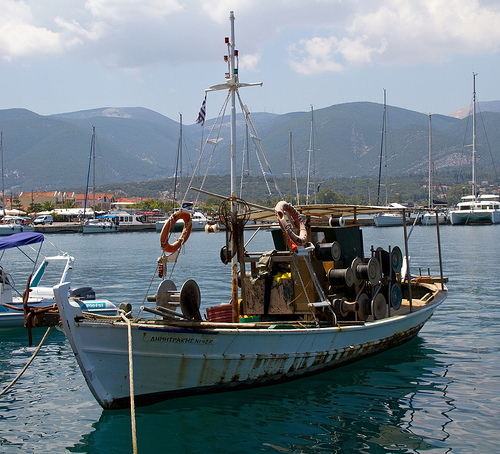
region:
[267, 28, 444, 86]
The sky is clear.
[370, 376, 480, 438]
The water is calm.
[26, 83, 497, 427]
Many boats are in the water.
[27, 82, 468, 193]
The mountains are far.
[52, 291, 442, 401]
The boat is white.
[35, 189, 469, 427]
The boat is in the water.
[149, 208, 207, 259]
The life saver is red.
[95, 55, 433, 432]
The boat has equipment on it.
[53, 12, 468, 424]
The boat is tethered to the shore.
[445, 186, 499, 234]
The boat is white.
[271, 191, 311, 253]
round orange life ring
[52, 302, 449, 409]
white boat with rusty bottom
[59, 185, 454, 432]
boat in a harbor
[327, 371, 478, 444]
deep blue water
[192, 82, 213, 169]
american flag on a post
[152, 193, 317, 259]
two orange life rings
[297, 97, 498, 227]
many boats in a row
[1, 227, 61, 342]
boat with purple roof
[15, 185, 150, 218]
buildings with orange roofs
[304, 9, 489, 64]
white fluffy clouds in sky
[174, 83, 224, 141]
A flag.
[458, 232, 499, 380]
The water is blue.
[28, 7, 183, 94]
The sky is cloudy.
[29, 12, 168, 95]
The sky is blue.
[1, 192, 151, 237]
A lot of boats in the background.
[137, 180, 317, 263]
Boat has life preservers.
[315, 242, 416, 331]
Boat has empty spools.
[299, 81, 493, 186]
Mountains are in the distance.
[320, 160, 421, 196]
Trees are in the distance.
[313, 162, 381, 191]
The trees are green.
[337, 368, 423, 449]
the water is clear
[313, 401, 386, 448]
the water is clear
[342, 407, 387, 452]
the water is clear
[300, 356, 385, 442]
the water is clear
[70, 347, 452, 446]
Boat's reflection in the water.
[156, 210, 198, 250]
Red life saving ring.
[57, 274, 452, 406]
A rusty white boat.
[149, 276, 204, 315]
An empty rope spool.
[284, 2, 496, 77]
White clouds in the sky.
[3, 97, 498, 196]
A range of low mountains in the background.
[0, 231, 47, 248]
Purple canopy on a boat.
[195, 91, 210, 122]
A striped flag on a boat.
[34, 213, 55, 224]
A light colored van.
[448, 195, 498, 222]
A white yacht.